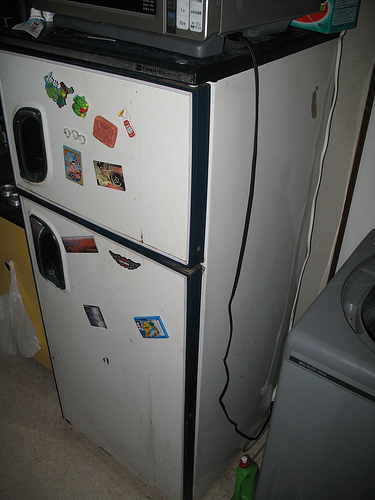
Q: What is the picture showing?
A: A refrigerator.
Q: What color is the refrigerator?
A: White and black.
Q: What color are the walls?
A: White.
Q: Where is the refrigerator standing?
A: On the floor.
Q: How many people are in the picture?
A: None.